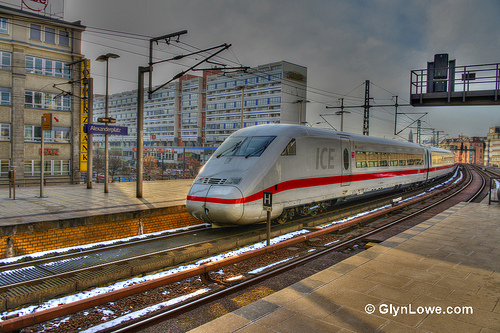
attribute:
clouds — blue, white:
[214, 6, 445, 108]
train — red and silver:
[120, 57, 498, 289]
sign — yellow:
[76, 57, 93, 172]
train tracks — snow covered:
[50, 254, 327, 314]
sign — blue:
[87, 91, 161, 179]